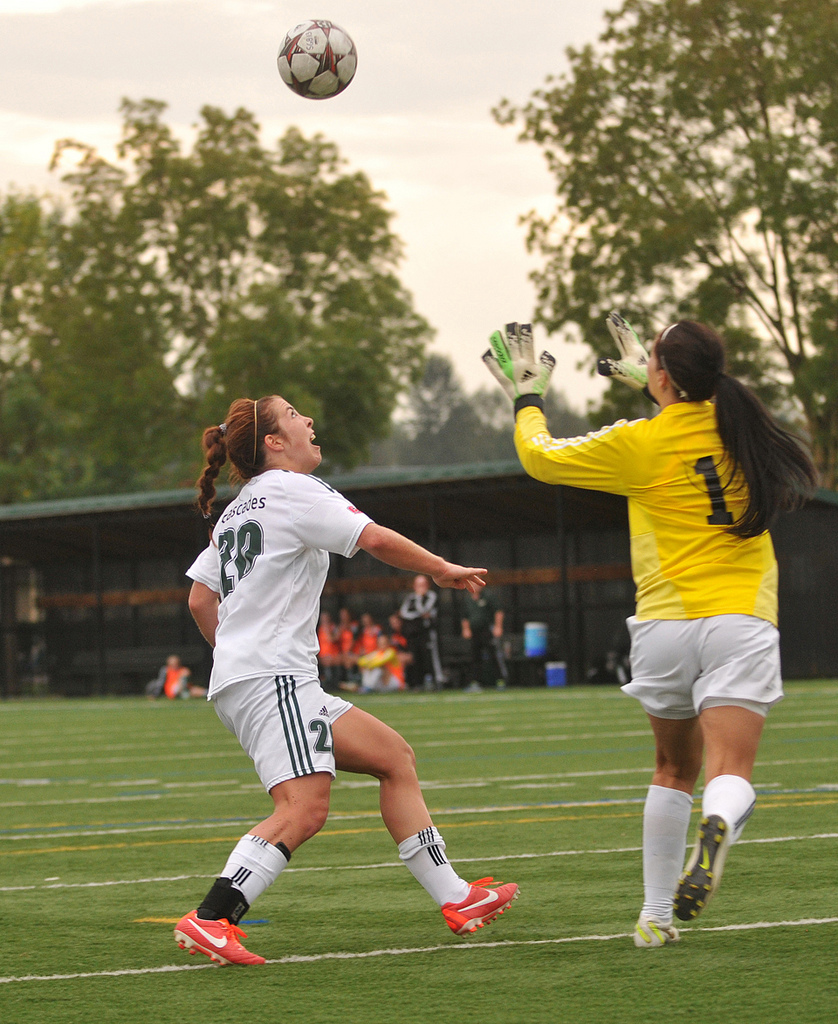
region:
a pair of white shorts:
[624, 609, 784, 709]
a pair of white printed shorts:
[210, 676, 350, 793]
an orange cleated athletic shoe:
[177, 907, 265, 966]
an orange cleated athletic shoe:
[439, 876, 519, 938]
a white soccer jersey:
[184, 471, 371, 699]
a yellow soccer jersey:
[514, 403, 782, 624]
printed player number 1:
[687, 453, 733, 528]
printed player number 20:
[218, 520, 262, 596]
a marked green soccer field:
[4, 678, 837, 1022]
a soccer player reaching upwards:
[478, 313, 819, 954]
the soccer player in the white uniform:
[153, 394, 516, 965]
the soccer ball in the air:
[276, 19, 359, 101]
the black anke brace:
[196, 874, 253, 926]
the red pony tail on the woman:
[199, 422, 226, 536]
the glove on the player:
[477, 323, 563, 407]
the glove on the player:
[593, 313, 654, 396]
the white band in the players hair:
[658, 320, 680, 390]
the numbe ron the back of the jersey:
[216, 522, 267, 602]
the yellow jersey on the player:
[515, 400, 780, 627]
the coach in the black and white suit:
[397, 571, 446, 691]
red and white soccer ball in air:
[249, 3, 363, 99]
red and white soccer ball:
[267, 24, 356, 99]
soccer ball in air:
[278, 10, 360, 106]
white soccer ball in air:
[264, 24, 368, 110]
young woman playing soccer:
[156, 376, 504, 966]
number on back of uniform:
[210, 509, 281, 619]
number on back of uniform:
[681, 454, 742, 536]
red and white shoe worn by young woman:
[435, 870, 533, 965]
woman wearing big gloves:
[476, 278, 806, 567]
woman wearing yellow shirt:
[509, 245, 832, 727]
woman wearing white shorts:
[588, 304, 823, 954]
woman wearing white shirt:
[184, 375, 535, 991]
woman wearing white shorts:
[167, 386, 501, 979]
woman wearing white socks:
[152, 367, 483, 976]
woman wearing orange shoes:
[158, 374, 512, 1004]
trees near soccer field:
[25, 272, 177, 459]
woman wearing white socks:
[590, 305, 801, 955]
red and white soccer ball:
[243, 5, 361, 112]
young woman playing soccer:
[502, 290, 810, 962]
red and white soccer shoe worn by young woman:
[155, 902, 280, 994]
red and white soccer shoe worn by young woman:
[417, 871, 523, 932]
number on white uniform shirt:
[212, 515, 279, 597]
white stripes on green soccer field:
[66, 934, 174, 997]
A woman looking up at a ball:
[156, 341, 428, 979]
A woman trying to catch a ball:
[542, 332, 774, 943]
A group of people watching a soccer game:
[271, 579, 530, 708]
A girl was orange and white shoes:
[161, 834, 503, 974]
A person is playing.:
[139, 380, 512, 984]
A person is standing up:
[456, 274, 782, 967]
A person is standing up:
[400, 571, 456, 685]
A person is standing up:
[456, 565, 523, 676]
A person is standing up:
[357, 611, 382, 672]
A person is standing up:
[377, 611, 408, 679]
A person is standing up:
[336, 609, 368, 684]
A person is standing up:
[319, 612, 340, 676]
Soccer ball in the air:
[273, 17, 367, 116]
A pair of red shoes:
[134, 853, 531, 987]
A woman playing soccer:
[167, 428, 418, 924]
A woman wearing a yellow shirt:
[495, 342, 806, 895]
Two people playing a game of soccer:
[143, 338, 789, 1020]